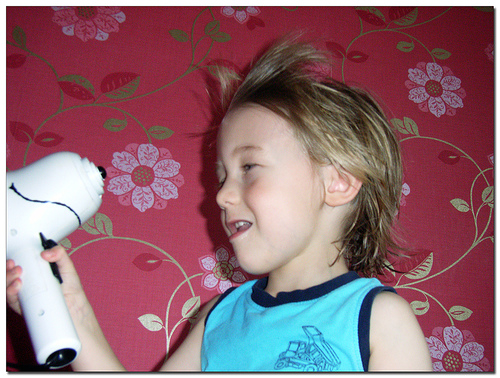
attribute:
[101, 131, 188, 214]
flower — pink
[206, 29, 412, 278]
hair — wet, light brown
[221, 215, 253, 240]
mouth — open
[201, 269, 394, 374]
t-shirt — round neck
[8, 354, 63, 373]
wire — black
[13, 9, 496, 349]
background — pink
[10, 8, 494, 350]
wall — multi color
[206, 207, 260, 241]
mouth — open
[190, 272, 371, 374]
shirt — light blue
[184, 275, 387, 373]
top — blue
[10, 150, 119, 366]
hair dryer — plastic, white, black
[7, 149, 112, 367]
blower — plastic, white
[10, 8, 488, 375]
surface — red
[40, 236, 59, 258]
button — black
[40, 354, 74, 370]
cord — black